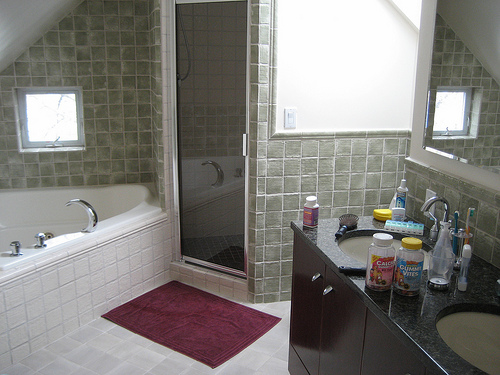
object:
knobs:
[323, 285, 332, 297]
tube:
[389, 177, 408, 210]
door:
[163, 0, 251, 287]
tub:
[2, 181, 168, 375]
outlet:
[280, 104, 303, 138]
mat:
[99, 280, 283, 367]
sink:
[442, 307, 499, 373]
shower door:
[169, 2, 252, 279]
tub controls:
[66, 196, 97, 235]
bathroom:
[0, 0, 500, 375]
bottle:
[365, 232, 394, 293]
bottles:
[396, 237, 426, 296]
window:
[16, 82, 85, 154]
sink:
[345, 220, 431, 262]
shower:
[168, 0, 419, 300]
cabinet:
[285, 211, 500, 372]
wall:
[0, 0, 162, 182]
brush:
[335, 212, 358, 239]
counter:
[291, 210, 494, 374]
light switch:
[283, 107, 298, 131]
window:
[432, 87, 482, 139]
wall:
[427, 14, 495, 164]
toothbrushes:
[466, 205, 475, 243]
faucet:
[65, 196, 99, 234]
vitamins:
[367, 232, 425, 296]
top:
[400, 236, 423, 249]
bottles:
[428, 221, 455, 291]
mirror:
[433, 92, 471, 136]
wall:
[280, 140, 400, 225]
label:
[399, 262, 420, 279]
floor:
[11, 280, 289, 375]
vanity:
[367, 253, 421, 294]